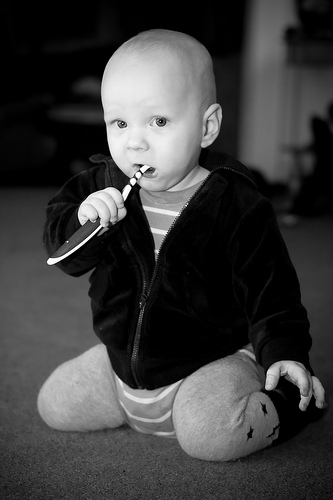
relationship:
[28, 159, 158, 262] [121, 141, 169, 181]
brush in mouth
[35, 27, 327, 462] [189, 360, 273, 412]
baby has thigh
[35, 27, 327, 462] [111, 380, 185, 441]
baby has crotch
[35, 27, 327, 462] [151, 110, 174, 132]
baby has eye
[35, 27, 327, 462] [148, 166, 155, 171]
baby brushing teeth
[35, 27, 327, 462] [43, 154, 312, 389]
baby wears jacket